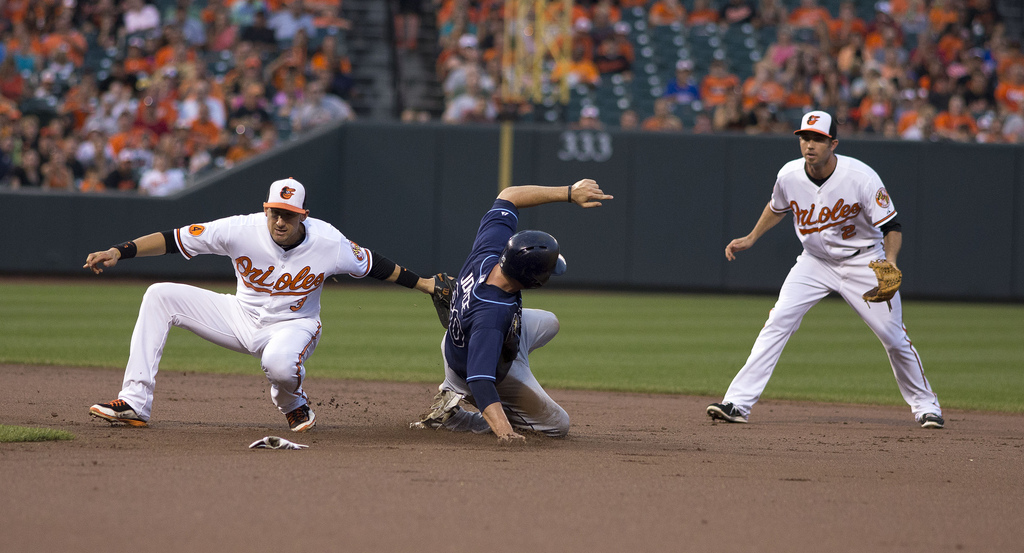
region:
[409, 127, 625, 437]
player in blue and grey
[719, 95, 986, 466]
player in white with tan mitt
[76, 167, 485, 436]
player in white with black mitt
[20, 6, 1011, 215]
spectators in the stands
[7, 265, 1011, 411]
green grass of field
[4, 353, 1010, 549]
dirt of baseball field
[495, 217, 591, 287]
blue batting helmet worn by player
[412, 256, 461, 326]
black mitt on hand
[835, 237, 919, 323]
tan mitt on hand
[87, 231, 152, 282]
black band on arm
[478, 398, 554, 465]
a man's hand on the ground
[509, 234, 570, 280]
a man wearing a helmet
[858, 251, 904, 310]
a man wearing a baseball glove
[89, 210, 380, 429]
a man kneeling on to the ground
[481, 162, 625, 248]
a man with his arm raised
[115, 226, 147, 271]
a man wearing a wrist band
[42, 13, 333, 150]
several people sitting in bleacher seats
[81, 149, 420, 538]
The player to the left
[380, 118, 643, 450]
The player in blue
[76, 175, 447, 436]
a man is playing baseball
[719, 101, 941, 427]
a man is playing baseball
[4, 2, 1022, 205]
crowd watching the game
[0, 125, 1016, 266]
the wall is green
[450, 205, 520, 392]
the shirt is blue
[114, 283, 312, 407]
the pants are white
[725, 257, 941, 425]
the pants are white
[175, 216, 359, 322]
the shirt is white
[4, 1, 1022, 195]
people seated in stands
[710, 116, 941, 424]
baseball player in white uniform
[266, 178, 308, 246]
baseball hat on head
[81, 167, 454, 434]
the man is wearing a black glove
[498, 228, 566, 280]
the helmet is black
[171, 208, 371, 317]
the jersey is white with orange letters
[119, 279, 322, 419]
the baseball pants are white with orange stripes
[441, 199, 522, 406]
the jersey is dark blue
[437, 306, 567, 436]
the pants are gray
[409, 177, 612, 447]
the man is wearing a blue jersey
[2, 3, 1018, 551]
the people playing on the baseball field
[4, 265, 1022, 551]
the green grass and the brown dirt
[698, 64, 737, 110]
A person is sitting down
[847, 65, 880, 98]
A person is sitting down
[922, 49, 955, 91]
A person is sitting down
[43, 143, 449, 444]
baseball player in white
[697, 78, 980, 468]
baseball player in white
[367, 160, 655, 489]
baseball player in blue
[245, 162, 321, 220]
white and orange colored hat on player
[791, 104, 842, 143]
white and orange colored hat on player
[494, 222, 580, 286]
blue colored helmet on player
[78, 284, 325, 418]
white colored pants on player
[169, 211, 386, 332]
white colored jersey on player